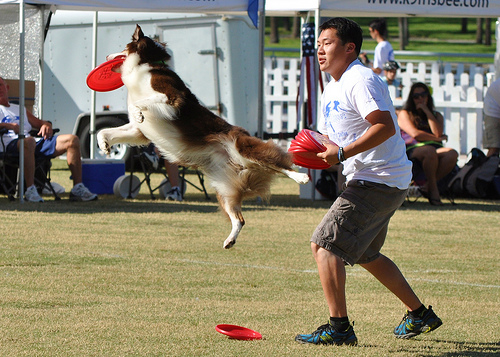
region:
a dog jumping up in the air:
[91, 22, 296, 244]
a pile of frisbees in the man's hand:
[283, 124, 330, 168]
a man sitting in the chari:
[0, 77, 97, 209]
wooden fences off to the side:
[259, 52, 498, 155]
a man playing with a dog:
[296, 21, 443, 342]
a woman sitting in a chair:
[396, 77, 461, 206]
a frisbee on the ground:
[216, 321, 260, 341]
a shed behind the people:
[45, 5, 257, 169]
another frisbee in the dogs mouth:
[88, 55, 123, 97]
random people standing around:
[366, 25, 402, 87]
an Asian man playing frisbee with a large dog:
[86, 10, 452, 342]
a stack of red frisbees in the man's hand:
[286, 128, 331, 166]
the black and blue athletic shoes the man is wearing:
[289, 298, 448, 355]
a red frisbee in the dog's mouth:
[78, 58, 130, 97]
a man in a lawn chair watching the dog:
[1, 71, 96, 219]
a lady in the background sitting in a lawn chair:
[392, 73, 468, 210]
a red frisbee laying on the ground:
[212, 320, 268, 345]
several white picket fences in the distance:
[265, 60, 309, 140]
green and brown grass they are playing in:
[18, 220, 172, 353]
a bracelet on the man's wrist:
[335, 141, 345, 165]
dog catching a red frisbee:
[82, 18, 300, 246]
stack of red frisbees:
[286, 122, 339, 172]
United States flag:
[296, 4, 321, 135]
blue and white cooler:
[69, 151, 135, 199]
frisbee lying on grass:
[190, 308, 273, 350]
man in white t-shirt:
[302, 13, 415, 195]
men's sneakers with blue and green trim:
[277, 295, 466, 355]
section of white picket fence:
[435, 78, 487, 150]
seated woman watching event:
[394, 81, 461, 212]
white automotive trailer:
[28, 6, 271, 167]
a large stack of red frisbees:
[286, 128, 338, 168]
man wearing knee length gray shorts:
[308, 178, 409, 265]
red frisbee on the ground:
[216, 320, 261, 340]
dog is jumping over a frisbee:
[79, 24, 308, 248]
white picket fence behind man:
[266, 58, 498, 163]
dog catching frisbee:
[83, 57, 125, 92]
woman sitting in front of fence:
[395, 82, 460, 204]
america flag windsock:
[296, 21, 328, 127]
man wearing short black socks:
[330, 315, 347, 328]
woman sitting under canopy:
[300, 0, 498, 198]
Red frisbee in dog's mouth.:
[85, 45, 157, 163]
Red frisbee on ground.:
[192, 282, 271, 337]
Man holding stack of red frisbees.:
[297, 130, 331, 212]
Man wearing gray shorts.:
[301, 197, 373, 251]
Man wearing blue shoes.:
[295, 308, 347, 354]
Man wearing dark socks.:
[314, 306, 349, 327]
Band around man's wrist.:
[333, 137, 347, 188]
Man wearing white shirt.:
[316, 80, 373, 181]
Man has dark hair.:
[301, 30, 362, 51]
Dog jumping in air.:
[92, 65, 259, 313]